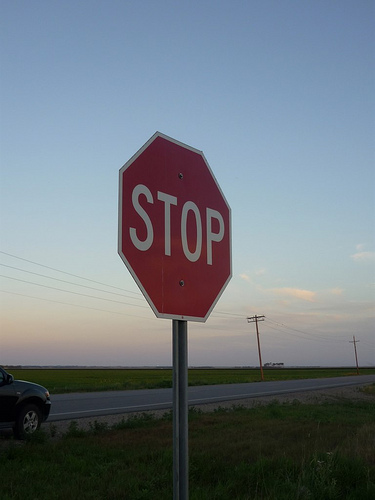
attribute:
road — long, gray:
[56, 374, 371, 406]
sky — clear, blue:
[1, 3, 372, 284]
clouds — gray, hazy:
[0, 305, 373, 365]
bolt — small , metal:
[180, 271, 193, 289]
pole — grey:
[77, 96, 296, 419]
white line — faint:
[55, 162, 254, 277]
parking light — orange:
[43, 388, 52, 399]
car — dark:
[1, 384, 45, 431]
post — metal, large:
[163, 317, 208, 498]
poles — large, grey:
[249, 312, 357, 377]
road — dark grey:
[0, 371, 374, 427]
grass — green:
[11, 400, 362, 491]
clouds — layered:
[253, 271, 369, 356]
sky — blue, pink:
[2, 2, 371, 357]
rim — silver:
[25, 408, 38, 430]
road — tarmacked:
[28, 372, 374, 411]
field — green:
[3, 361, 347, 392]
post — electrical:
[346, 334, 363, 367]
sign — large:
[103, 127, 246, 332]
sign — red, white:
[116, 130, 232, 323]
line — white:
[49, 377, 374, 417]